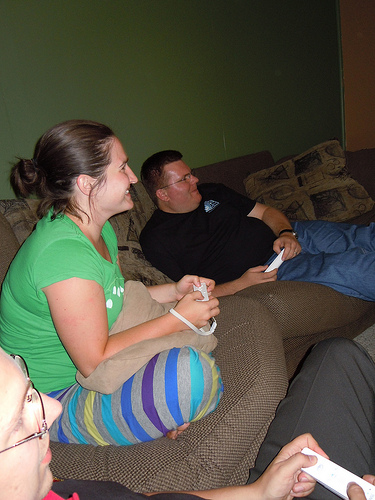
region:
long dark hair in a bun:
[10, 118, 116, 221]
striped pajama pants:
[42, 347, 222, 445]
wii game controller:
[296, 446, 369, 496]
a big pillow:
[243, 135, 372, 222]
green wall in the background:
[0, 1, 341, 201]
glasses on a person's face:
[0, 353, 49, 453]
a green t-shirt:
[0, 209, 124, 393]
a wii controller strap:
[170, 307, 218, 336]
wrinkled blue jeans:
[263, 219, 374, 300]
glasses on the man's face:
[162, 168, 197, 189]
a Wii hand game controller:
[300, 448, 373, 499]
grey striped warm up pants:
[63, 346, 224, 446]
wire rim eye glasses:
[7, 354, 47, 454]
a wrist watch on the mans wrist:
[277, 226, 297, 238]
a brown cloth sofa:
[222, 293, 365, 432]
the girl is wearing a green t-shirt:
[1, 206, 125, 354]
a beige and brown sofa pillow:
[244, 136, 371, 221]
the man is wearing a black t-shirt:
[139, 189, 276, 273]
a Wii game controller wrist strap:
[168, 306, 217, 338]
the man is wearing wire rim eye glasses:
[160, 168, 195, 192]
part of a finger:
[285, 460, 292, 471]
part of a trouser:
[294, 409, 300, 418]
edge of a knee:
[217, 379, 223, 385]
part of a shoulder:
[314, 384, 320, 386]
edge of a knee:
[201, 416, 204, 422]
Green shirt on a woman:
[5, 208, 129, 388]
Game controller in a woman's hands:
[189, 279, 210, 302]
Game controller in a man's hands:
[301, 443, 362, 499]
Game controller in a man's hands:
[262, 244, 287, 274]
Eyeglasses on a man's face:
[160, 170, 193, 185]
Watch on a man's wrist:
[281, 226, 299, 238]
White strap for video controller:
[167, 309, 217, 336]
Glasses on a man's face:
[0, 351, 47, 453]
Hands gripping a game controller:
[176, 276, 219, 322]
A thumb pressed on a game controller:
[283, 452, 316, 469]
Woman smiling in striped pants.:
[4, 113, 232, 438]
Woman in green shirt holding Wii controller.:
[6, 113, 234, 442]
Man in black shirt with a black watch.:
[137, 143, 369, 290]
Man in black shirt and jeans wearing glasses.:
[139, 146, 343, 288]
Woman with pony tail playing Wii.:
[2, 106, 238, 443]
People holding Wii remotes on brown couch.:
[2, 115, 373, 485]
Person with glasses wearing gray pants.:
[0, 336, 372, 499]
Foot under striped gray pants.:
[39, 345, 243, 438]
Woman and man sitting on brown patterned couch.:
[4, 111, 372, 449]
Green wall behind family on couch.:
[0, 81, 359, 465]